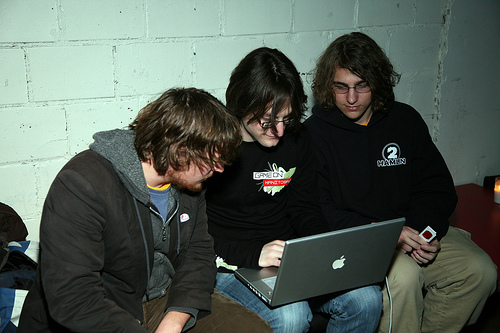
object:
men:
[62, 24, 497, 332]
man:
[39, 93, 235, 332]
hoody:
[52, 129, 225, 332]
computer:
[234, 212, 407, 309]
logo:
[324, 249, 351, 270]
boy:
[301, 30, 496, 332]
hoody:
[308, 100, 457, 254]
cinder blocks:
[2, 1, 498, 179]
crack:
[422, 2, 452, 146]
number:
[383, 145, 401, 160]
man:
[205, 48, 384, 330]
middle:
[214, 37, 377, 332]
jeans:
[217, 267, 383, 332]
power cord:
[375, 275, 396, 332]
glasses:
[332, 81, 372, 95]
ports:
[244, 278, 269, 307]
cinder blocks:
[438, 8, 499, 183]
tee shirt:
[147, 183, 176, 223]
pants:
[376, 224, 498, 332]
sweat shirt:
[202, 131, 336, 268]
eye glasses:
[254, 116, 298, 131]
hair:
[134, 87, 243, 176]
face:
[174, 147, 225, 194]